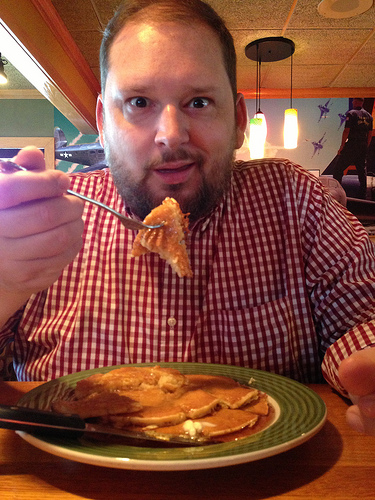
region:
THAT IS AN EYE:
[120, 88, 152, 123]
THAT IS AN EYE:
[187, 88, 211, 121]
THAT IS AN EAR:
[91, 95, 101, 140]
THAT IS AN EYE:
[237, 93, 257, 141]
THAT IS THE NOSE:
[155, 114, 188, 147]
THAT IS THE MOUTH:
[138, 145, 197, 186]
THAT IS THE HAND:
[5, 146, 87, 300]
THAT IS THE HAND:
[325, 235, 367, 426]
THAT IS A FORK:
[73, 189, 154, 230]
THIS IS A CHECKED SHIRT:
[251, 196, 290, 292]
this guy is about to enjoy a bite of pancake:
[94, 0, 251, 291]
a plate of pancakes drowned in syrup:
[12, 360, 331, 473]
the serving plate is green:
[10, 359, 329, 472]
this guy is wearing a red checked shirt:
[4, 153, 373, 377]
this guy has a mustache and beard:
[99, 129, 239, 228]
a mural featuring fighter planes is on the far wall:
[301, 98, 350, 172]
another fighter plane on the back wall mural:
[53, 120, 115, 172]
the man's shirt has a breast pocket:
[214, 292, 305, 377]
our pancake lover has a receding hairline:
[91, 1, 251, 227]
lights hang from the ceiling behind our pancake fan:
[240, 33, 301, 159]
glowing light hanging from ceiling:
[249, 38, 299, 156]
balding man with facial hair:
[101, 0, 240, 228]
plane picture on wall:
[302, 99, 351, 159]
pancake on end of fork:
[121, 199, 189, 274]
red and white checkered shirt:
[5, 155, 372, 377]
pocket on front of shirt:
[222, 295, 297, 362]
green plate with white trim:
[14, 361, 329, 469]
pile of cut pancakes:
[64, 364, 267, 440]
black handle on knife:
[3, 403, 210, 449]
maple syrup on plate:
[222, 408, 275, 439]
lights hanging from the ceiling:
[226, 23, 314, 156]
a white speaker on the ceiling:
[318, 0, 372, 30]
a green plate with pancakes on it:
[8, 340, 341, 490]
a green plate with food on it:
[23, 341, 320, 495]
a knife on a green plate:
[6, 359, 270, 475]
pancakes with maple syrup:
[56, 330, 260, 466]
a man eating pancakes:
[65, 64, 239, 310]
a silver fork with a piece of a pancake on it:
[21, 159, 267, 314]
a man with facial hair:
[91, 39, 235, 235]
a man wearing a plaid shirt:
[9, 69, 372, 443]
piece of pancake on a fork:
[131, 195, 195, 274]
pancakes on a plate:
[53, 364, 268, 442]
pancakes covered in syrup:
[55, 365, 270, 442]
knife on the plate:
[0, 405, 219, 447]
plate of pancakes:
[11, 357, 321, 463]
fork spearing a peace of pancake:
[3, 158, 165, 237]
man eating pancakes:
[0, 1, 374, 427]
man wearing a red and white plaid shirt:
[0, 0, 374, 431]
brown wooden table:
[1, 381, 373, 497]